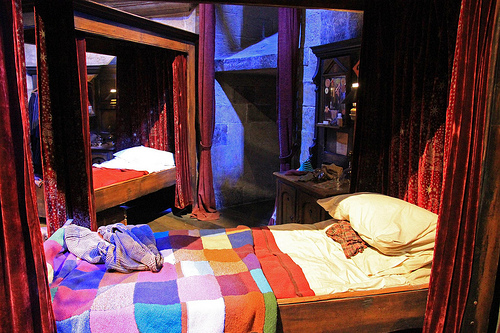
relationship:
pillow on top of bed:
[113, 147, 177, 167] [30, 143, 188, 216]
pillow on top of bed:
[317, 191, 439, 256] [40, 219, 439, 333]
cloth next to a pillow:
[325, 220, 369, 258] [317, 191, 439, 256]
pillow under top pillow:
[314, 219, 434, 284] [317, 191, 439, 256]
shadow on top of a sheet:
[268, 219, 337, 230] [266, 218, 433, 295]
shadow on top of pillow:
[316, 188, 380, 217] [317, 191, 439, 256]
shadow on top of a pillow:
[313, 220, 338, 231] [314, 219, 434, 284]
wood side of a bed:
[277, 289, 426, 332] [40, 219, 439, 333]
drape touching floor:
[189, 3, 220, 223] [132, 203, 278, 229]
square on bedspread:
[134, 303, 181, 333] [40, 225, 275, 333]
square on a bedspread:
[223, 291, 265, 333] [40, 225, 275, 333]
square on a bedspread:
[186, 297, 226, 333] [40, 225, 275, 333]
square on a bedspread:
[176, 274, 224, 303] [40, 225, 275, 333]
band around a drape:
[279, 156, 295, 165] [268, 2, 301, 224]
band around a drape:
[198, 141, 213, 154] [189, 3, 220, 223]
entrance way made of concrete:
[196, 2, 300, 223] [196, 0, 279, 208]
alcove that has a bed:
[33, 0, 209, 216] [30, 143, 188, 216]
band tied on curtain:
[279, 142, 300, 164] [268, 2, 301, 224]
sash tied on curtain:
[198, 141, 213, 154] [189, 3, 220, 223]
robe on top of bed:
[64, 222, 166, 273] [40, 219, 439, 333]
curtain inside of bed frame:
[117, 55, 193, 209] [33, 0, 209, 216]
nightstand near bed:
[274, 170, 353, 225] [40, 219, 439, 333]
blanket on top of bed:
[40, 225, 275, 333] [40, 219, 439, 333]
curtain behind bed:
[356, 1, 484, 264] [40, 219, 439, 333]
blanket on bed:
[91, 166, 150, 192] [30, 143, 188, 216]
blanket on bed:
[252, 225, 315, 302] [40, 219, 439, 333]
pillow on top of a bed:
[317, 191, 439, 256] [40, 219, 439, 333]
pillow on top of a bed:
[113, 147, 177, 167] [30, 143, 188, 216]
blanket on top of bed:
[91, 166, 150, 192] [30, 143, 188, 216]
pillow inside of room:
[113, 147, 177, 167] [1, 0, 500, 330]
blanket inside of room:
[91, 166, 150, 192] [1, 0, 500, 330]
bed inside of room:
[40, 219, 439, 333] [1, 0, 500, 330]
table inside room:
[91, 138, 118, 164] [1, 0, 500, 330]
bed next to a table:
[40, 219, 439, 333] [274, 170, 353, 225]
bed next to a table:
[30, 143, 188, 216] [91, 138, 118, 164]